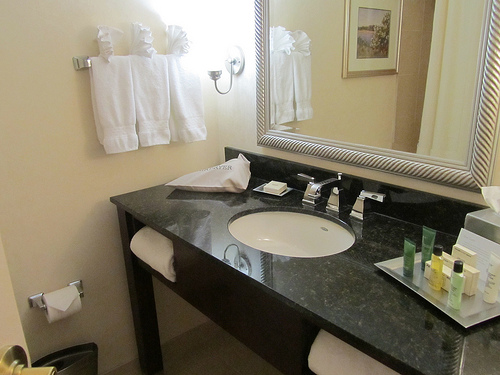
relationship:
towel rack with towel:
[71, 52, 97, 71] [165, 52, 212, 145]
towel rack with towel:
[71, 52, 97, 71] [126, 52, 176, 150]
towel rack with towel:
[71, 52, 97, 71] [87, 53, 144, 156]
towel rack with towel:
[71, 52, 97, 71] [162, 23, 194, 61]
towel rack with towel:
[71, 52, 97, 71] [128, 18, 157, 61]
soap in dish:
[263, 177, 290, 196] [252, 179, 295, 199]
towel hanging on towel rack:
[165, 52, 212, 145] [71, 52, 97, 71]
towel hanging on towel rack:
[126, 52, 176, 150] [71, 52, 97, 71]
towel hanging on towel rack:
[87, 53, 144, 156] [71, 52, 97, 71]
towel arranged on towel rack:
[165, 52, 212, 145] [71, 52, 97, 71]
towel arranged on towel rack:
[126, 52, 176, 150] [71, 52, 97, 71]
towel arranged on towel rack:
[87, 53, 144, 156] [71, 52, 97, 71]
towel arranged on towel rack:
[162, 23, 194, 61] [71, 52, 97, 71]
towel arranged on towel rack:
[128, 18, 157, 61] [71, 52, 97, 71]